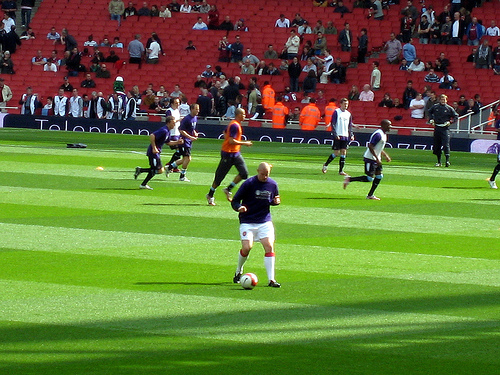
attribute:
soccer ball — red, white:
[238, 271, 259, 291]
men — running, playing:
[131, 95, 251, 213]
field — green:
[1, 122, 496, 373]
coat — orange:
[272, 101, 288, 128]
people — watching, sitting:
[261, 11, 373, 90]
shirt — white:
[371, 68, 382, 85]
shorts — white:
[237, 220, 279, 245]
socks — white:
[232, 247, 280, 280]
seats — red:
[47, 0, 84, 19]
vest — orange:
[221, 120, 244, 154]